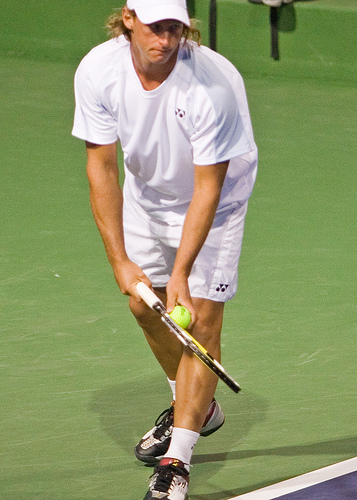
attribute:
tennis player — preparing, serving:
[66, 1, 261, 497]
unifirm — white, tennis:
[72, 0, 257, 498]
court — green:
[16, 6, 349, 474]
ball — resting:
[165, 299, 194, 331]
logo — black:
[203, 270, 254, 299]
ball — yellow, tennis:
[170, 304, 191, 329]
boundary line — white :
[230, 455, 355, 498]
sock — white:
[167, 424, 201, 468]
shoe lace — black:
[153, 464, 182, 488]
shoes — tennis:
[134, 397, 225, 499]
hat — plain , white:
[128, 8, 197, 37]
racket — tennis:
[132, 280, 245, 395]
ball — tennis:
[167, 303, 191, 328]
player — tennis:
[71, 1, 272, 498]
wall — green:
[4, 0, 355, 84]